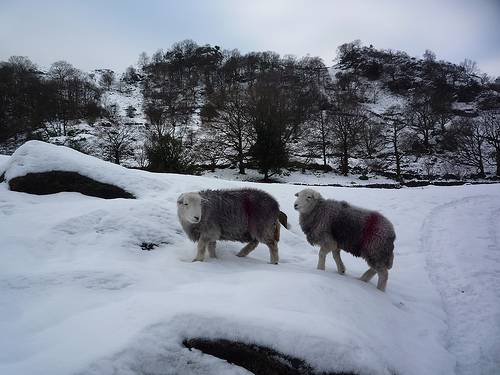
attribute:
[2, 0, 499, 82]
sky — blue, large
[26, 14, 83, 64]
clouds — white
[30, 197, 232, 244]
rock — smaller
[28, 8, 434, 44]
sky — blue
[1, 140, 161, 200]
rock — large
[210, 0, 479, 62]
cloud — white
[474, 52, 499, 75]
cloud — white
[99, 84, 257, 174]
mountain — snow-covered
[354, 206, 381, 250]
stripe — red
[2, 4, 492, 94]
sky — blue, cloudy, cold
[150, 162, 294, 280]
sheep — lead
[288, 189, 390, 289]
sheep — gray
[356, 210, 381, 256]
spot — red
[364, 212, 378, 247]
marker — red, paint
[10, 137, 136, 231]
rock — snow-covered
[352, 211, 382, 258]
stripe — dark orange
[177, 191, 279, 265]
sheep — gray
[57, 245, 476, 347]
snow — white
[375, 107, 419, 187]
tree — leafless, large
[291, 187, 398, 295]
sheep — white, brown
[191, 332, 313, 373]
wedge — dark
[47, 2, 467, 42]
sky — blue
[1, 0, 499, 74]
clouds — white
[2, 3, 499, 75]
sky — blue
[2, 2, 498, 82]
clouds — white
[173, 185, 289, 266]
sheep — brown, white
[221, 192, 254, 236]
stripe — red